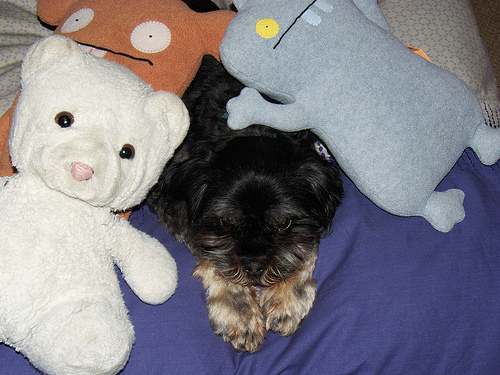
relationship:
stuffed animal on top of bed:
[0, 35, 190, 374] [2, 0, 499, 374]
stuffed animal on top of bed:
[1, 1, 237, 178] [2, 0, 499, 374]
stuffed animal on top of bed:
[218, 2, 498, 235] [2, 0, 499, 374]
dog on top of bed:
[144, 55, 344, 354] [2, 0, 499, 374]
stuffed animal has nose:
[0, 35, 190, 374] [71, 161, 94, 183]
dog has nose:
[144, 55, 344, 354] [245, 260, 264, 274]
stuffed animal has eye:
[218, 2, 498, 235] [256, 17, 280, 40]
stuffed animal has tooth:
[218, 2, 498, 235] [313, 0, 336, 11]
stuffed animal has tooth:
[218, 2, 498, 235] [300, 8, 321, 26]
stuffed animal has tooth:
[1, 1, 237, 178] [76, 41, 91, 52]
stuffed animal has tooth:
[1, 1, 237, 178] [90, 46, 106, 58]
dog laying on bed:
[144, 55, 344, 354] [2, 0, 499, 374]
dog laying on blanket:
[144, 55, 344, 354] [0, 148, 498, 375]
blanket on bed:
[0, 148, 498, 375] [2, 0, 499, 374]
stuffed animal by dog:
[0, 35, 190, 374] [144, 55, 344, 354]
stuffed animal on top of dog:
[0, 35, 190, 374] [144, 55, 344, 354]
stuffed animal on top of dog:
[1, 1, 237, 178] [144, 55, 344, 354]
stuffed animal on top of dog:
[218, 2, 498, 235] [144, 55, 344, 354]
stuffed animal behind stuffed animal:
[1, 1, 237, 178] [0, 35, 190, 374]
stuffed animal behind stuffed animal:
[218, 2, 498, 235] [0, 35, 190, 374]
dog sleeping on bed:
[144, 55, 344, 354] [2, 0, 499, 374]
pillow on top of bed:
[2, 2, 56, 116] [2, 0, 499, 374]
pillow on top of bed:
[376, 2, 499, 129] [2, 0, 499, 374]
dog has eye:
[144, 55, 344, 354] [277, 217, 293, 230]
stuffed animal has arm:
[0, 35, 190, 374] [107, 211, 179, 303]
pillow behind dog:
[2, 2, 56, 116] [144, 55, 344, 354]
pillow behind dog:
[376, 2, 499, 129] [144, 55, 344, 354]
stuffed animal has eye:
[1, 1, 237, 178] [131, 21, 173, 56]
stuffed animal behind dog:
[1, 1, 237, 178] [144, 55, 344, 354]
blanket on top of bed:
[0, 148, 498, 375] [2, 0, 499, 374]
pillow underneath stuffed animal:
[2, 2, 56, 116] [0, 35, 190, 374]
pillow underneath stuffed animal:
[2, 2, 56, 116] [1, 1, 237, 178]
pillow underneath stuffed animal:
[376, 2, 499, 129] [218, 2, 498, 235]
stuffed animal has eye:
[1, 1, 237, 178] [61, 7, 97, 33]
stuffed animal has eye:
[0, 35, 190, 374] [53, 111, 75, 129]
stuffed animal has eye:
[0, 35, 190, 374] [119, 143, 135, 161]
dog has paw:
[144, 55, 344, 354] [258, 279, 315, 337]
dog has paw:
[144, 55, 344, 354] [205, 289, 267, 355]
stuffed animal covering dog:
[0, 35, 190, 374] [144, 55, 344, 354]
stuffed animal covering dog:
[1, 1, 237, 178] [144, 55, 344, 354]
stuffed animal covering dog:
[218, 2, 498, 235] [144, 55, 344, 354]